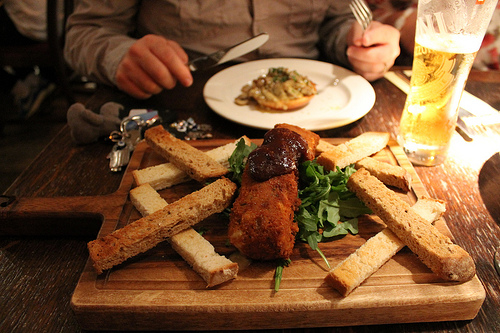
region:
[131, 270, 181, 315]
edge o0f a board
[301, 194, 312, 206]
this is a leaf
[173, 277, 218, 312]
p-art of a line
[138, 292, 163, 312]
part of a board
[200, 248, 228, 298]
part of a cakae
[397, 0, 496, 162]
A glass of beer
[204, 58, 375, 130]
Food on the plate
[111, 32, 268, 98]
A knife in the person's hand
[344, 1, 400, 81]
A fork in the person's hand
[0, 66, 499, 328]
A table beneath the food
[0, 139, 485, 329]
A tray beneath the food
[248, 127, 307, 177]
Red sauce on the food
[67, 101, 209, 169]
Keys on the table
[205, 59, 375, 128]
The plate is circular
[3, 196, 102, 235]
A handle on the tray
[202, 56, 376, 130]
White plate with food on it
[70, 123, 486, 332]
Wooden plate with food on it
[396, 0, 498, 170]
Tall glass containing beer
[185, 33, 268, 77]
Silver knife being held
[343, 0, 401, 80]
Silver fork being held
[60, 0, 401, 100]
Man holding knife and fork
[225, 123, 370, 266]
Meat with lettuce underneath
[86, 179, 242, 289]
Breadsticks sitting on plate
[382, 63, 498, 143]
White paper nakin with fork on it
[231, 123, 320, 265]
Piece of meat with BBQ sauce on top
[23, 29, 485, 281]
this is a dinner meal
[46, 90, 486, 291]
this is a healthy meal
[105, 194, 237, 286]
these are bread sticks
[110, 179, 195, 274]
the bread sticks are brown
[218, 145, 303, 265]
this is breaded meat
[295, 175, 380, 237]
these are vegetables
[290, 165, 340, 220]
the lettuce is green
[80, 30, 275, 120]
the man is holding a knife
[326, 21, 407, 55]
the man is holding a fork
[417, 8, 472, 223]
this is a beer